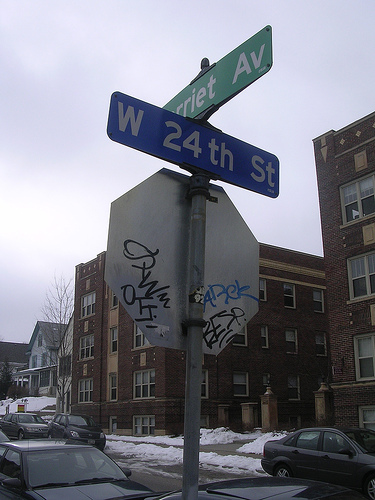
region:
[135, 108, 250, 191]
blue and white street sign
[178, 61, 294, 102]
green and white street sign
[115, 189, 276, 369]
grafitti and back of street sign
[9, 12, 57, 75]
white clouds in blue sky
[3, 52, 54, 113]
white clouds in blue sky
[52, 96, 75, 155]
white clouds in blue sky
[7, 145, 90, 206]
white clouds in blue sky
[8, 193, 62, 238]
white clouds in blue sky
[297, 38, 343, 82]
white clouds in blue sky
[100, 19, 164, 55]
white clouds in blue sky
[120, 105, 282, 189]
blue and white sign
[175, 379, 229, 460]
silver pole on the sign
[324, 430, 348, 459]
window on the car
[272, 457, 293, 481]
tire on the car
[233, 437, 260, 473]
snow on the ground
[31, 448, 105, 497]
front window of the car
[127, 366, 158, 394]
window on the building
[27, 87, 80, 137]
sky above the building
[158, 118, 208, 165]
the number 24 on the sign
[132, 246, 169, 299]
writing on the back of the sign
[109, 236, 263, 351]
black and blue grafitti on the back of a stopsign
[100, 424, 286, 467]
snow has been cleared from the sidewalks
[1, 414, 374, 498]
cars parked on both sides of the street facing the same way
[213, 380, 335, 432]
stone columns in front of a building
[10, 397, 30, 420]
real estate sign in a yard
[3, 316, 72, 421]
houses line the street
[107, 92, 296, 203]
the blue sign says "W 24th St"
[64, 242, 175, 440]
the front of a four-story red brick building with some windows facing the street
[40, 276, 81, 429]
the bare tree indicates that it is winter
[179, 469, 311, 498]
the car parked by the stopsign has a sunroof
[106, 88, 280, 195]
a blue and white street name sign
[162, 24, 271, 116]
a green and white street name sign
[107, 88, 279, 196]
W 24th St street sign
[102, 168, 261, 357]
back of street sign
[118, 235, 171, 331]
black marked graffiti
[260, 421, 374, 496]
a black car in street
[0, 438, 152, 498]
a parked black car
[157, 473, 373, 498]
a parked black car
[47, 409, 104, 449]
a parked black SUV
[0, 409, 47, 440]
a parked grey car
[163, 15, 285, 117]
a sign on a green sign.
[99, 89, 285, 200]
a blue street sign.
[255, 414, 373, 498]
a car parked in the snow.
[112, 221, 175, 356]
graffiti on a stop sign.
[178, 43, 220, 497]
a metal pole near a street.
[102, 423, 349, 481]
a sidewalk covered in snow.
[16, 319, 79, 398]
a multi story building.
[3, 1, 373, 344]
a gray cloudy sky.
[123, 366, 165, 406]
windows on the front of a building.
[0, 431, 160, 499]
a car parked near a stop sign.